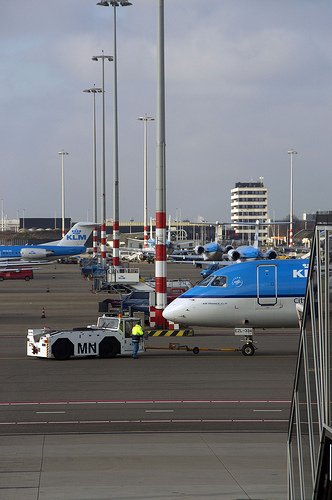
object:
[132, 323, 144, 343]
coat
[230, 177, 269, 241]
tower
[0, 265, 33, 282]
van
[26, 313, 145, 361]
vehicle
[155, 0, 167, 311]
post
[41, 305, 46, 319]
cone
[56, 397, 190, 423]
lines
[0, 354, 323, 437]
runway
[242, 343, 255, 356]
tire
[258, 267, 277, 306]
door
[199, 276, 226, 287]
windshield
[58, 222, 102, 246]
tail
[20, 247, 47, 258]
booster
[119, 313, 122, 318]
light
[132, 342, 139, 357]
pants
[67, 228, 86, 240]
logo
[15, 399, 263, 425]
stripes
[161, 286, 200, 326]
nose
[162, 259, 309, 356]
airplane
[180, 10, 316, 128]
sky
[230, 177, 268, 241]
building